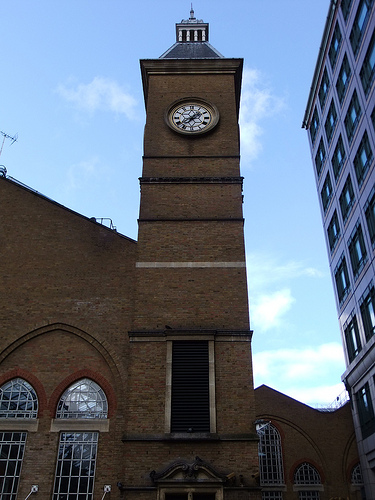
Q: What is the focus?
A: Clock tower.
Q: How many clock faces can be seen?
A: 1.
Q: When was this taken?
A: Daytime.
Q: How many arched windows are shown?
A: 5.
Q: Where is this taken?
A: Front of the tower.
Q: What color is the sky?
A: Blue.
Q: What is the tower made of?
A: Brick.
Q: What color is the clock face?
A: White.